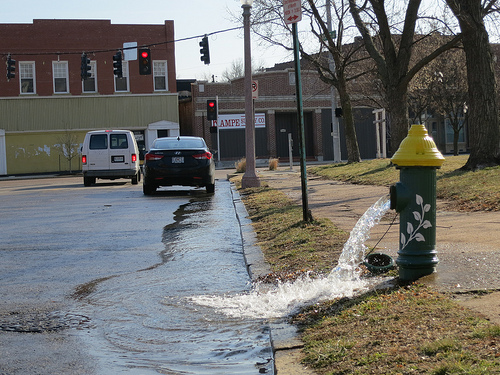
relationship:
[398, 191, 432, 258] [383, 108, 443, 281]
flower panted on the hydrant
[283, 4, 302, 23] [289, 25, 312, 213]
sign on a pole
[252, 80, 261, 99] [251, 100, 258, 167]
sign on a pole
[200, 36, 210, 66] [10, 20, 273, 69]
lights on the wire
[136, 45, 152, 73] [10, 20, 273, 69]
lights on the wire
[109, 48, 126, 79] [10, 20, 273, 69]
lights on the wire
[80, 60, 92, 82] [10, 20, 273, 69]
lights on the wire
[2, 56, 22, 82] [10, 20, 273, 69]
lights on the wire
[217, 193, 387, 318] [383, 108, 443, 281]
water coming from hydrant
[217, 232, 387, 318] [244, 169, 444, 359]
water on the ground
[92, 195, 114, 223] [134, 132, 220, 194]
shadow next to car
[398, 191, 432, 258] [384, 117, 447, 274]
flower on the hydrant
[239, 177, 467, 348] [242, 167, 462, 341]
grass on the ground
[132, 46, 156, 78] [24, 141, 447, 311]
light above land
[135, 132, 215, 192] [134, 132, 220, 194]
back of the car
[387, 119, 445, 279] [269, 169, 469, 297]
fire hydrant on sidewalk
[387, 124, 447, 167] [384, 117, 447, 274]
top of hydrant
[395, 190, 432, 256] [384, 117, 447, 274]
plant painted on hydrant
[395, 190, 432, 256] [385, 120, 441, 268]
plant on hydrant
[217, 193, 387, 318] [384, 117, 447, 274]
water pouring from hydrant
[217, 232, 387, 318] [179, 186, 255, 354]
water on road side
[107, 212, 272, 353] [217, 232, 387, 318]
puddle of water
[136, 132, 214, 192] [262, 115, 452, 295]
car beside sidewalk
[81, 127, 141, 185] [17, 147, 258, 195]
van at intersection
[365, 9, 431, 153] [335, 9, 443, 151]
tree of a tree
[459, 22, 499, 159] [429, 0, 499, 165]
bark on tree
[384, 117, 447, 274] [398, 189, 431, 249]
hydrant has design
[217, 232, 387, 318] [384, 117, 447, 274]
water flowing out of hydrant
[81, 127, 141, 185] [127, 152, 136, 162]
van has brake light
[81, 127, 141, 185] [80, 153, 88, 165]
van has brake light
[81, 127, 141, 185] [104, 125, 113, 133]
van has brake light